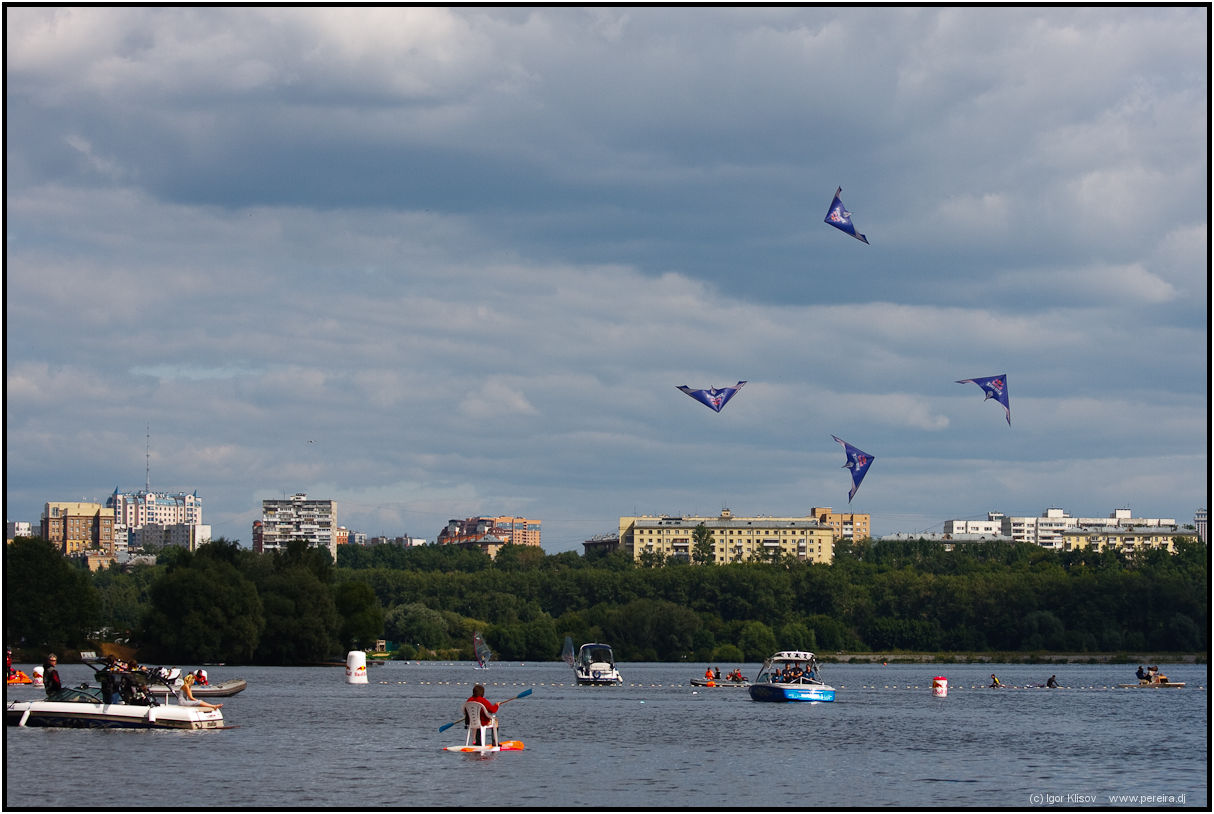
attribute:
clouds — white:
[75, 245, 732, 408]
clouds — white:
[23, 13, 1124, 284]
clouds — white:
[290, 339, 1159, 489]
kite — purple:
[669, 366, 755, 430]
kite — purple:
[815, 423, 883, 498]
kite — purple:
[952, 366, 1018, 427]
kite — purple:
[813, 178, 881, 246]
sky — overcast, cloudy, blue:
[16, 24, 1177, 489]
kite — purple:
[674, 366, 749, 414]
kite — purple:
[826, 426, 878, 505]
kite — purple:
[954, 361, 1022, 433]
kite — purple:
[828, 426, 880, 498]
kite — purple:
[669, 359, 755, 414]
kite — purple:
[956, 361, 1028, 425]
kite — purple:
[804, 180, 865, 248]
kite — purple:
[660, 357, 746, 416]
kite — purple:
[822, 430, 877, 505]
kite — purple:
[950, 370, 1020, 427]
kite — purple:
[817, 180, 876, 250]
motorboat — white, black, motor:
[11, 684, 233, 745]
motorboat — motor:
[749, 646, 839, 707]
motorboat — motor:
[565, 626, 622, 690]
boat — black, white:
[9, 682, 231, 741]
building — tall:
[245, 483, 348, 571]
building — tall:
[616, 492, 838, 573]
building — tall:
[42, 492, 123, 562]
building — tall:
[102, 481, 210, 551]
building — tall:
[435, 498, 538, 544]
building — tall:
[250, 483, 347, 555]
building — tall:
[429, 501, 550, 551]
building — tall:
[627, 496, 841, 579]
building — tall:
[40, 494, 123, 569]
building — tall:
[98, 478, 212, 548]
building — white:
[106, 481, 214, 547]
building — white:
[945, 492, 1170, 556]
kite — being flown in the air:
[679, 366, 751, 421]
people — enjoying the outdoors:
[74, 635, 981, 791]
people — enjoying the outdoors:
[442, 635, 1015, 807]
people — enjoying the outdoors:
[12, 648, 1047, 804]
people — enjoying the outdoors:
[10, 644, 899, 809]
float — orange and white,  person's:
[449, 739, 532, 761]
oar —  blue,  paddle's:
[520, 690, 533, 703]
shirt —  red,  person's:
[463, 690, 507, 729]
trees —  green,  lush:
[0, 536, 1209, 650]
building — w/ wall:
[953, 518, 1014, 544]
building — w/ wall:
[953, 523, 1005, 549]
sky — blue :
[47, 56, 1174, 546]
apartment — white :
[248, 471, 360, 614]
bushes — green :
[356, 590, 559, 671]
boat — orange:
[439, 724, 531, 761]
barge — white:
[0, 682, 242, 730]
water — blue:
[0, 644, 1209, 802]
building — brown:
[428, 503, 544, 555]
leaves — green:
[489, 558, 555, 628]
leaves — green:
[611, 545, 710, 611]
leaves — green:
[617, 611, 683, 650]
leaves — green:
[723, 609, 780, 648]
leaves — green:
[783, 569, 862, 617]